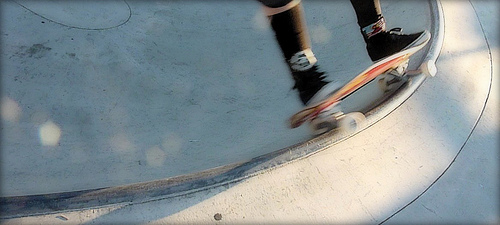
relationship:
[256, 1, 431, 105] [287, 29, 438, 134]
legs on skateboard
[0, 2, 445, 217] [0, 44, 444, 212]
ramp has edge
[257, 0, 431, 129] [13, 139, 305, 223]
skateboarder has shadow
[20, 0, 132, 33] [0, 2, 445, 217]
pattern in pool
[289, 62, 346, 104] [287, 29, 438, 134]
shoe on skateboard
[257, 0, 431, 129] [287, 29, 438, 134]
person on skateboard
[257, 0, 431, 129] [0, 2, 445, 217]
person skateboarding in pool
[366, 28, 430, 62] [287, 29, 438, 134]
sneaker on skateboard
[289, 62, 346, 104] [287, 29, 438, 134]
sneaker on skateboard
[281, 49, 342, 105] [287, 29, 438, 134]
foot on skateboard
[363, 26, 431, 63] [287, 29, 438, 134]
foot on skateboard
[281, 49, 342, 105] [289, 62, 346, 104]
foot in sneaker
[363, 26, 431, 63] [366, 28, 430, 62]
foot in sneaker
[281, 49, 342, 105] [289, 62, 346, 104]
foot in shoe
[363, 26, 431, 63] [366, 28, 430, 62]
foot in shoe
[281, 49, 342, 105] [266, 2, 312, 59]
foot in sock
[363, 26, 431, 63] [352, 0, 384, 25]
foot in sock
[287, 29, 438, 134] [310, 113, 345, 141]
skateboard has wheel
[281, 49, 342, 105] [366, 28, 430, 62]
foot in sneaker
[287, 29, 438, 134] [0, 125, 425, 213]
skateboard on rail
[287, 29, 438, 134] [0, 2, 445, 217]
skateboard on ramp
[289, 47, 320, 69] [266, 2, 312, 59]
detail on sock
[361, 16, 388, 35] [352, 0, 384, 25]
detail on sock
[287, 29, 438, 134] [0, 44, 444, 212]
skateboard has edge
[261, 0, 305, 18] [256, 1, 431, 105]
skin on legs